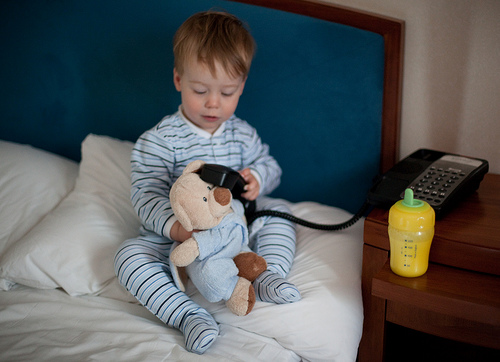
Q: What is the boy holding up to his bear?
A: A phone.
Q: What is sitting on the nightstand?
A: A cup and a telephone.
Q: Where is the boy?
A: Sitting on the bed.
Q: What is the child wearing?
A: Blue and white pajamas.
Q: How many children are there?
A: One.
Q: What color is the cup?
A: Yellow.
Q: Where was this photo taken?
A: In a hotel room.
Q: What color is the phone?
A: Black.